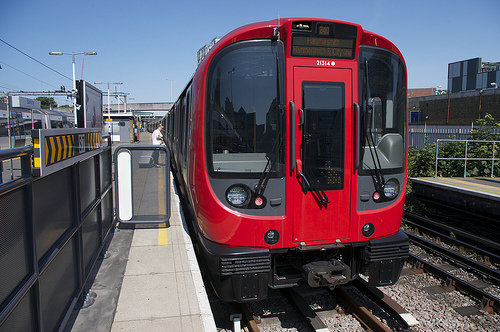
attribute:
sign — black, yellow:
[26, 122, 117, 169]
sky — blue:
[110, 6, 185, 70]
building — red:
[423, 46, 496, 130]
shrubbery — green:
[412, 117, 499, 168]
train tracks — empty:
[402, 209, 497, 329]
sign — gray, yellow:
[28, 127, 104, 176]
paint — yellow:
[155, 150, 170, 245]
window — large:
[202, 37, 286, 178]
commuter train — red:
[144, 14, 414, 312]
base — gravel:
[390, 258, 498, 330]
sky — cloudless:
[1, 4, 497, 102]